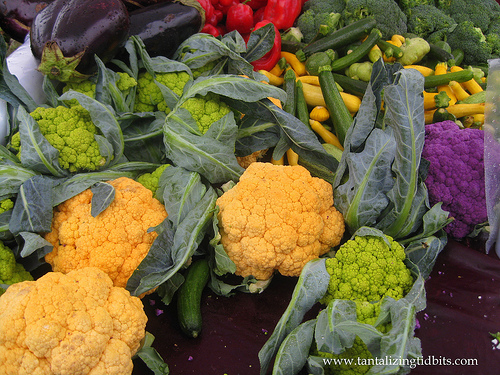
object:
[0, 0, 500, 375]
vegetables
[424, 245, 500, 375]
floor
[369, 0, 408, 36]
broccoli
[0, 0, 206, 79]
eggplant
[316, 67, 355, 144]
squash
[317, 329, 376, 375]
cauliflower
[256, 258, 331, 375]
leaf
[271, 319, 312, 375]
leaf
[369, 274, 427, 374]
leaf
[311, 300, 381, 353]
leaf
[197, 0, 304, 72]
pepper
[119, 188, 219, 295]
leaves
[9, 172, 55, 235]
leaves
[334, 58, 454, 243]
leaves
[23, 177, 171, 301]
cauliflower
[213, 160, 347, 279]
cauliflower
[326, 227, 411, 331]
cauliflower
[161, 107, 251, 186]
leaves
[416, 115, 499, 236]
cauliflower